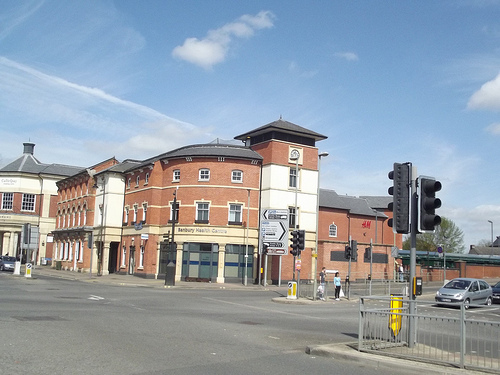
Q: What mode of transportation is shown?
A: Van.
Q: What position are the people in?
A: Standing.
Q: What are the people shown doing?
A: Walking.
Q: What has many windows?
A: Building.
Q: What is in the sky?
A: Clouds.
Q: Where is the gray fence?
A: Near the signal sign.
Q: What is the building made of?
A: Bricks.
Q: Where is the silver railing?
A: Below the traffic signal.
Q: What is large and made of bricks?
A: The building.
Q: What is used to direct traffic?
A: The traffic lights.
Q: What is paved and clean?
A: The street.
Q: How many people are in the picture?
A: Two.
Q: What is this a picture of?
A: City scape.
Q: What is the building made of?
A: Brick.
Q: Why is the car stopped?
A: Traffic signal.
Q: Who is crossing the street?
A: People.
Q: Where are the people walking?
A: Sidewalk.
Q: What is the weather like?
A: Sunny.